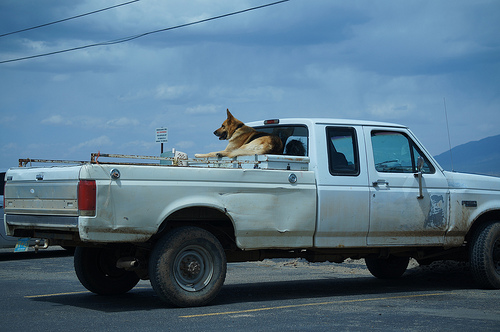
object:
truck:
[2, 116, 500, 308]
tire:
[148, 226, 225, 306]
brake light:
[77, 180, 96, 210]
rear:
[5, 163, 92, 237]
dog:
[194, 108, 278, 158]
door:
[364, 126, 448, 250]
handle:
[372, 180, 390, 187]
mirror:
[416, 157, 423, 172]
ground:
[1, 303, 497, 331]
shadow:
[33, 277, 499, 315]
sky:
[2, 2, 497, 167]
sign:
[155, 127, 167, 142]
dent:
[274, 186, 292, 231]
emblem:
[461, 200, 478, 208]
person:
[286, 139, 306, 155]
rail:
[90, 152, 259, 164]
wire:
[1, 46, 69, 66]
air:
[2, 3, 499, 331]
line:
[183, 291, 460, 317]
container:
[186, 155, 309, 171]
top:
[239, 119, 443, 173]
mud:
[160, 256, 167, 269]